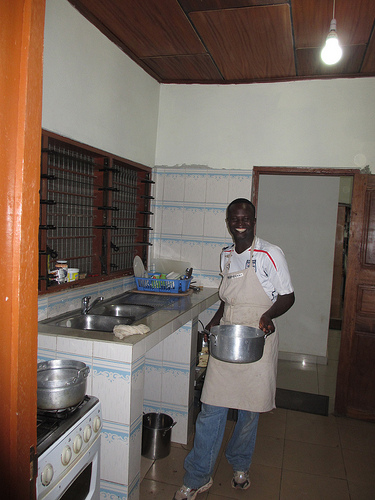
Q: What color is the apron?
A: Beige.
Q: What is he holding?
A: Pot.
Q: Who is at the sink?
A: The man.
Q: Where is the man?
A: In a kitchen.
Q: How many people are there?
A: One.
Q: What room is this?
A: Kitchen.